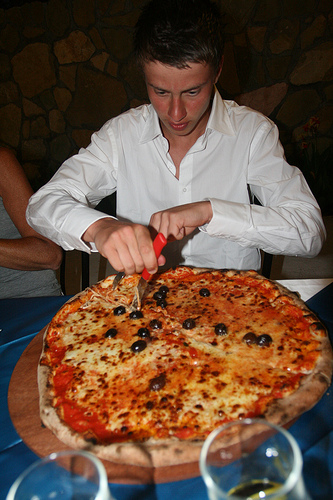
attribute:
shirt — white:
[27, 107, 327, 289]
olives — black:
[238, 328, 276, 349]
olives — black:
[152, 284, 215, 310]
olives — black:
[177, 313, 234, 339]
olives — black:
[100, 301, 166, 349]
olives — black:
[145, 370, 170, 392]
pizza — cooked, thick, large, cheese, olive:
[37, 261, 331, 469]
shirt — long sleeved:
[24, 92, 324, 270]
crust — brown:
[39, 382, 77, 432]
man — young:
[13, 11, 325, 297]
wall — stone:
[17, 20, 317, 191]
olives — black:
[102, 276, 270, 362]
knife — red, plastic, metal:
[127, 227, 168, 323]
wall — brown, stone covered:
[0, 3, 322, 220]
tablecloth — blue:
[1, 288, 329, 498]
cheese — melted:
[58, 280, 301, 433]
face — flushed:
[149, 63, 204, 130]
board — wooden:
[4, 331, 322, 478]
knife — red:
[123, 227, 170, 306]